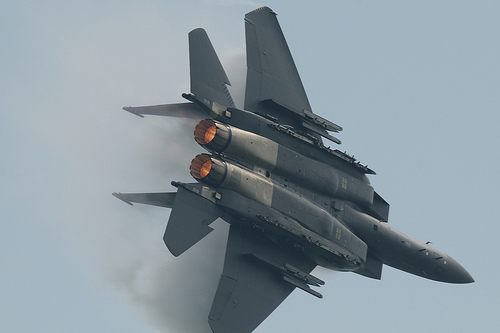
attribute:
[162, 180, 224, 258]
tail wing — sharp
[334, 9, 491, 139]
sky — clear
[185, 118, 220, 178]
light — orange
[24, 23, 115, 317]
background — solid blue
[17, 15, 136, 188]
sky — clear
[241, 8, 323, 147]
wing — triangular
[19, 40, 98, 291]
sky — clear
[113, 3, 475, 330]
jet — gray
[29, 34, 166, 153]
sky — clear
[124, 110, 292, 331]
smoke — gray, cloud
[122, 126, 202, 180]
cloud — dark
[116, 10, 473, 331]
rocket — big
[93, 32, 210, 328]
smoke — gray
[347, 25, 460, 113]
sky — clear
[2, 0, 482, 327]
sky — clear